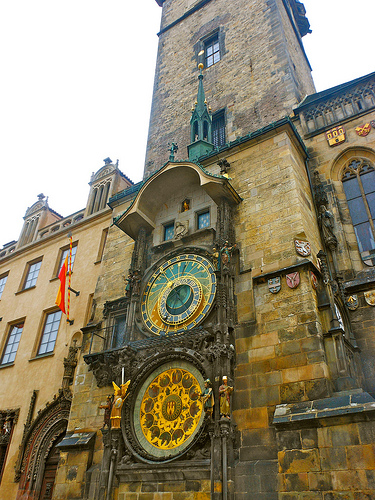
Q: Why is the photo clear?
A: Its during the day.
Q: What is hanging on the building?
A: A flag.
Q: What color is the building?
A: Brown.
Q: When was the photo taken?
A: Daytime.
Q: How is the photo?
A: Clear.